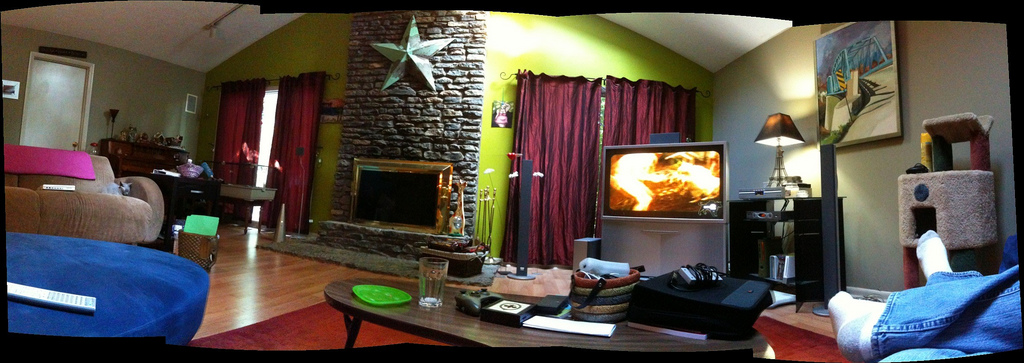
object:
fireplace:
[315, 10, 486, 261]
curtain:
[213, 71, 326, 234]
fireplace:
[348, 158, 453, 235]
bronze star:
[370, 14, 455, 92]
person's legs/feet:
[826, 230, 1024, 363]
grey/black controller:
[666, 262, 727, 291]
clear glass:
[418, 257, 450, 307]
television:
[600, 141, 731, 277]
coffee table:
[323, 277, 766, 359]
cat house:
[897, 111, 996, 290]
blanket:
[5, 145, 98, 180]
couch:
[1, 144, 166, 246]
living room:
[0, 0, 1024, 363]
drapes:
[258, 71, 326, 235]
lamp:
[755, 112, 806, 187]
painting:
[812, 21, 902, 148]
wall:
[710, 21, 1017, 292]